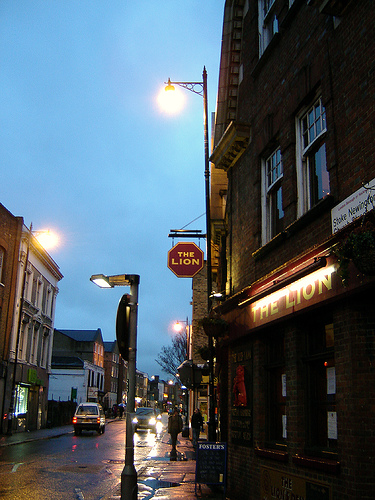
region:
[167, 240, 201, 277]
An eight sided business sign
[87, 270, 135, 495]
A street light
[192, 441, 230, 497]
A chalk board sign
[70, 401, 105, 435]
The back of a car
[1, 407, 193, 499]
A two lane street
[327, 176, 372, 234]
A white sign on a building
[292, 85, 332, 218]
A sliding window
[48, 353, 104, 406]
A white building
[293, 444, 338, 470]
An outdoor window sill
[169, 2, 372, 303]
The second story of a building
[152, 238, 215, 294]
a small red sign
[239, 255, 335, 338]
the sign to a restaurant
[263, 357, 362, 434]
the windows of a restaurant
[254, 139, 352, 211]
the windows of an apartment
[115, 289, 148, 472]
the pole to a street light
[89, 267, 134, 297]
the light of a street light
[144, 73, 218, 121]
a light that hangs high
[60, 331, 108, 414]
a big white building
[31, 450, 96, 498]
a small wet cement road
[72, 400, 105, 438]
a small yellow taxi car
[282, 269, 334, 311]
The word "LION" on a sign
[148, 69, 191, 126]
A light is turned on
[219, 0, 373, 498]
Brown bricks on a building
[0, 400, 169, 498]
Two cars on the road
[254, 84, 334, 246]
Two windows on a building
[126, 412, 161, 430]
Two headlights are turned on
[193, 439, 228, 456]
White writing on a black sign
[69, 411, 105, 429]
Two red rear lights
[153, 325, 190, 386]
A tree with no leaves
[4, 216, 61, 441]
A tall street lamp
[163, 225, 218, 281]
sign on a pole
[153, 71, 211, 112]
street light on a pole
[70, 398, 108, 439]
vehicle on a street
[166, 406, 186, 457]
person walking on a street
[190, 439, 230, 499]
advertising sign on a sidewalk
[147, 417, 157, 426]
front headlight on a vehicle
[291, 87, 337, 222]
window on a building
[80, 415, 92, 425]
licence plate on a vehicle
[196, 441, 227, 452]
lettering on a sign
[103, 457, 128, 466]
manhole lid in a street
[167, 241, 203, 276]
the red octagon sign sticking out from the building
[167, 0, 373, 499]
the building next to the octagon sign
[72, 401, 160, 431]
the cars on the road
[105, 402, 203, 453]
the people on the sidewalk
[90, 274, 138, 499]
the street light on the sidewalk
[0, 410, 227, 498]
the wetness on the ground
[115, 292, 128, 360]
the sign hanging on the street light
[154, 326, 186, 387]
the bare tree in the distance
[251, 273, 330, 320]
the words "THE LION" on the sign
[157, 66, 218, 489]
the tall lamp post next to the building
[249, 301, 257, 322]
white print style letter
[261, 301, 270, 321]
white print style letter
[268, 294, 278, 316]
white print style letter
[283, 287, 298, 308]
white print style letter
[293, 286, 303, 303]
white print style letter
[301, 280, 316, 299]
white print style letter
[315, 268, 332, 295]
white print style letter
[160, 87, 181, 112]
the light is on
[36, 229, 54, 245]
the light is on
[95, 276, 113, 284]
the light is on